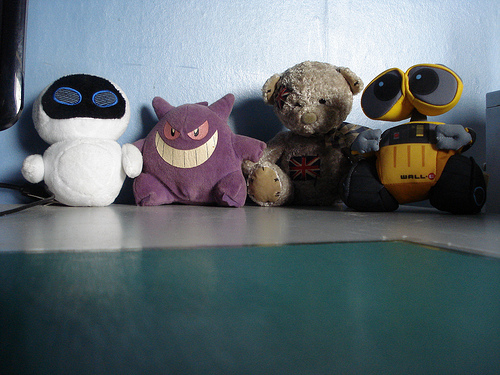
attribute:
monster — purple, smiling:
[130, 94, 269, 207]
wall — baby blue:
[2, 1, 498, 214]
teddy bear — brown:
[246, 59, 375, 214]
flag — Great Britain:
[282, 147, 339, 187]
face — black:
[43, 73, 126, 123]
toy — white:
[21, 74, 144, 203]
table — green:
[0, 200, 500, 373]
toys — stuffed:
[19, 61, 479, 225]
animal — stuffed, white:
[37, 109, 149, 218]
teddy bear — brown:
[239, 48, 397, 209]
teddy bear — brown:
[229, 59, 384, 204]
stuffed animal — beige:
[242, 60, 362, 206]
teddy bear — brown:
[253, 43, 379, 217]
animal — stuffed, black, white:
[20, 72, 144, 208]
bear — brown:
[240, 54, 387, 208]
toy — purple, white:
[130, 91, 269, 208]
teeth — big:
[153, 130, 218, 168]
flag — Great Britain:
[289, 152, 321, 178]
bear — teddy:
[261, 41, 387, 219]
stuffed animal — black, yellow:
[341, 61, 486, 216]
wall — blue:
[45, 3, 495, 89]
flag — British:
[282, 153, 324, 182]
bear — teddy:
[244, 59, 364, 208]